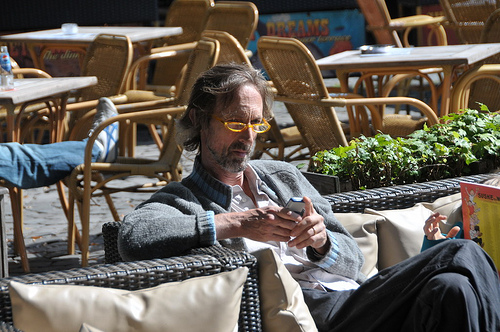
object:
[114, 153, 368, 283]
sweater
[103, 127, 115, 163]
stripes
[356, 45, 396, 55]
ashtray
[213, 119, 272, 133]
eyeglasses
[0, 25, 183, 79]
table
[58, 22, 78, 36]
holder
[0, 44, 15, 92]
bottle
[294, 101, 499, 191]
bush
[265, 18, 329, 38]
word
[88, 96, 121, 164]
foot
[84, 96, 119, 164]
sneaker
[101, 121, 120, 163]
designs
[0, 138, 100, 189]
leg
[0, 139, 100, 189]
jeans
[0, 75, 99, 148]
table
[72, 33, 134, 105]
backrest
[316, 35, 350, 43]
writing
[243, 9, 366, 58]
poster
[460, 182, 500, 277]
paper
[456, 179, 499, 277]
book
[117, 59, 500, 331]
man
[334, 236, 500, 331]
legs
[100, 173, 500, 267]
furniture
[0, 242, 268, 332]
chair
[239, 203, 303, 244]
hands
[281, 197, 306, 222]
cellphone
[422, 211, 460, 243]
child's hand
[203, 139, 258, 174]
beard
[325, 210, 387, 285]
pillow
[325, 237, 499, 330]
pants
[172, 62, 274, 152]
hair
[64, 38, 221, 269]
chair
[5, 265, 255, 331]
pillow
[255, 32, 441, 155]
chair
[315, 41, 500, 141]
table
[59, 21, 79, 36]
jar